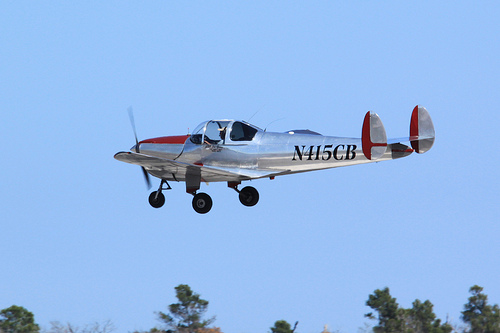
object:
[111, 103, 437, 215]
plane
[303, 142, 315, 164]
number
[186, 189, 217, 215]
tire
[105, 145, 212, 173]
wing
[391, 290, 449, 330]
tree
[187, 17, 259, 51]
sky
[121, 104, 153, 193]
propeller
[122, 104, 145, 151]
blades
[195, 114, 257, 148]
window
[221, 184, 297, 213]
wheel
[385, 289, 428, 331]
leaves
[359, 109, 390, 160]
tail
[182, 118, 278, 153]
cockpit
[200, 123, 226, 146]
man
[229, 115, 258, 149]
windshield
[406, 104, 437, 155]
fin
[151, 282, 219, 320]
trees